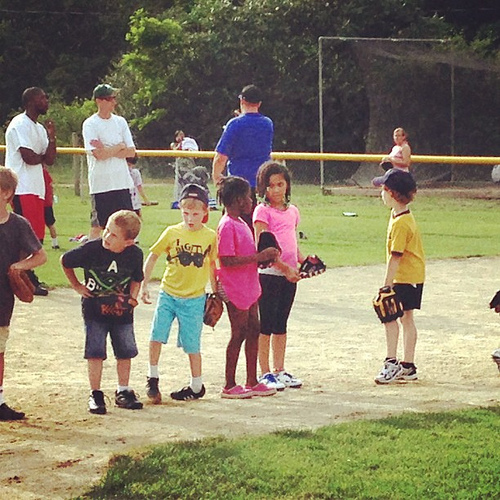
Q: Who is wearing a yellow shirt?
A: A boy.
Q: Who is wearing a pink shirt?
A: A girl.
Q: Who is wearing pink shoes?
A: A girl.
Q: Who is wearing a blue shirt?
A: A man.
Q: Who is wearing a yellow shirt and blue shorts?
A: A boy.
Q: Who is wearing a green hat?
A: A boy.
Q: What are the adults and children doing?
A: Playing on a field.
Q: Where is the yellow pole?
A: Across the park.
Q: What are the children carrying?
A: Mitts.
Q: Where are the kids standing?
A: On a baseball field.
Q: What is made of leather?
A: Baseball gloves.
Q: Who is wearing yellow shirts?
A: Two boys.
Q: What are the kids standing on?
A: Dirt.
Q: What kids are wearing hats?
A: Two boys in yellow.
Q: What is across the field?
A: A big tree.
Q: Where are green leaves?
A: On a tree.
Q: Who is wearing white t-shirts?
A: Two adult men on the left.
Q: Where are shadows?
A: On the dirt.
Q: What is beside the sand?
A: Green grass.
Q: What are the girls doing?
A: Talking.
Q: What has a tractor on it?
A: Yellow shirt.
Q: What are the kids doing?
A: Standing on a field.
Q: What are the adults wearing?
A: White T-Shirts.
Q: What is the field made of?
A: Sand.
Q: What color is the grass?
A: Green.